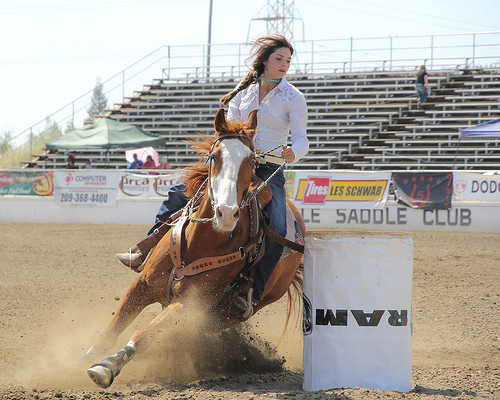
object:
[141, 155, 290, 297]
trousers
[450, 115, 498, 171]
tent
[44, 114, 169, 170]
tent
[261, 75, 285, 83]
neck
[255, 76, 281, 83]
necklace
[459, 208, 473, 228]
black letters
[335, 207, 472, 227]
saddle club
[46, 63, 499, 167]
stands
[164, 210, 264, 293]
bridle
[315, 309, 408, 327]
ram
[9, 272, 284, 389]
dust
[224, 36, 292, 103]
hair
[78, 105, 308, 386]
brown horse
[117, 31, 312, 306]
woman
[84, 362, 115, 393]
hoof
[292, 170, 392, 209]
advertisement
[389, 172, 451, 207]
advertisement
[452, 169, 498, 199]
advertisement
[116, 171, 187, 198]
advertisement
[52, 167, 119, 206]
advertisement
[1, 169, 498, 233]
wall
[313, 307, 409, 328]
writing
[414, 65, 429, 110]
woman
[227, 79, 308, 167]
shirt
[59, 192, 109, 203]
number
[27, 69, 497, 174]
bleachers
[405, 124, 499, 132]
benches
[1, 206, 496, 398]
ground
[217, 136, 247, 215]
white patch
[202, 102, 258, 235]
head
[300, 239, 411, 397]
barrel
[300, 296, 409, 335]
logo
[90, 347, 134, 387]
straps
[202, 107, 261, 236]
horse head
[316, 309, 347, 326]
word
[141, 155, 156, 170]
people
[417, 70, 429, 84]
shirt